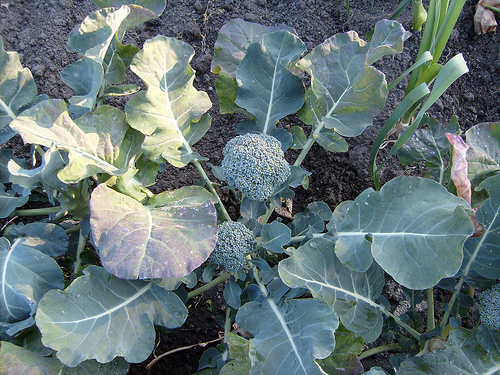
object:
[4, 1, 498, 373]
plant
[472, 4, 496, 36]
leaf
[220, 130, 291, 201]
broccoli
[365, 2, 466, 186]
grass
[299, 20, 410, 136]
leaf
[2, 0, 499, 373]
dirt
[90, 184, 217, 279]
leaf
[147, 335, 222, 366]
twig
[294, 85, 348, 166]
vein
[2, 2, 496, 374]
ground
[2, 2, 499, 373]
picture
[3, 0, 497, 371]
soil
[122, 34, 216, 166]
leaves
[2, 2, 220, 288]
sunshin